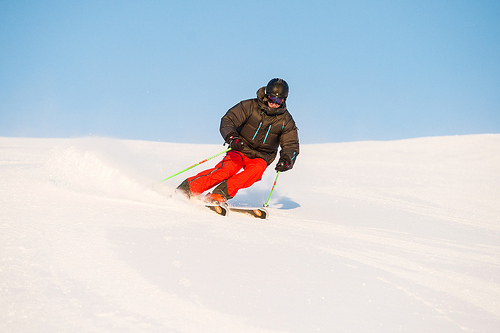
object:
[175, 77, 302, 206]
man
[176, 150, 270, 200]
pants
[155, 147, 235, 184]
pole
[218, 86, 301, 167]
jacket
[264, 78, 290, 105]
helmet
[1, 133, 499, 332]
snow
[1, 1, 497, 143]
sky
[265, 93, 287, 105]
goggles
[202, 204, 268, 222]
skis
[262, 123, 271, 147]
zipper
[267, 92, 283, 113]
face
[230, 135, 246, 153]
glove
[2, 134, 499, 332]
ground